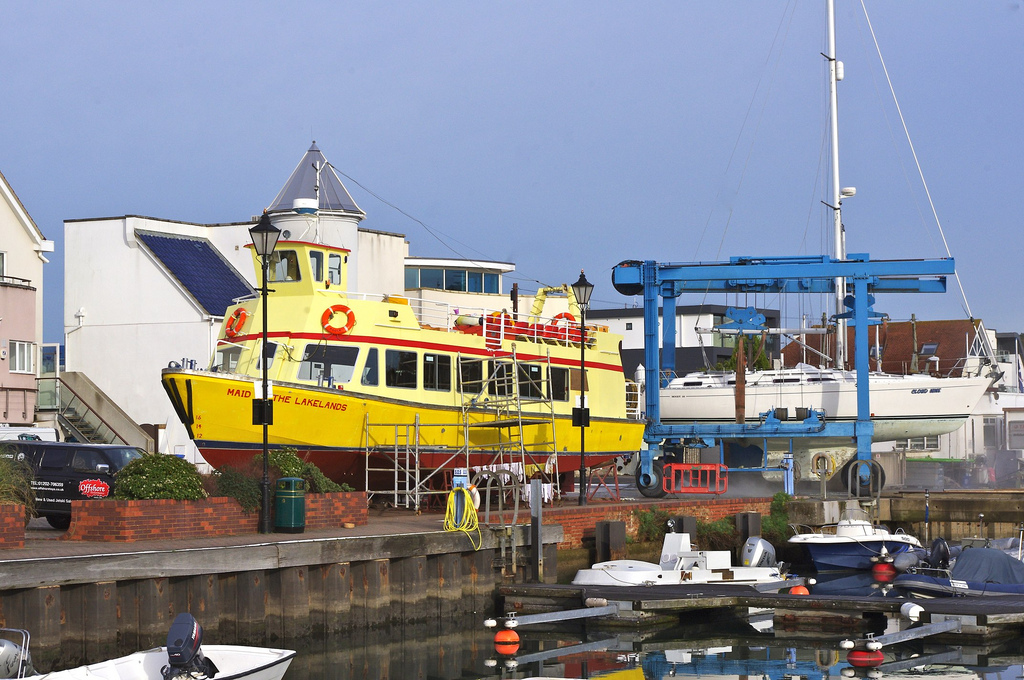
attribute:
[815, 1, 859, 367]
mast — tall, white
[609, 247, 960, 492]
structure — metal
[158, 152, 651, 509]
ship — painted, red, yellow, orange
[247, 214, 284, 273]
lamp — black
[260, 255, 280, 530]
post — tall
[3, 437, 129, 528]
van — black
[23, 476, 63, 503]
text — white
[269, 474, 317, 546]
bin — trash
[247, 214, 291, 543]
post — lamp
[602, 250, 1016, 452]
boat — large, white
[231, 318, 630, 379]
stripe — red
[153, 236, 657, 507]
boat — large, red, yellow, yellow and red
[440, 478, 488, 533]
rope — yellow 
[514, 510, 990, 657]
boats — big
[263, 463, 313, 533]
trashcan — green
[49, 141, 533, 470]
house — lg, white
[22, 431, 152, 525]
van — black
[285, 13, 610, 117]
sky — clear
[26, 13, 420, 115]
sky — clear, blue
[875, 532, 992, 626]
boat — blue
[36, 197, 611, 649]
building — white